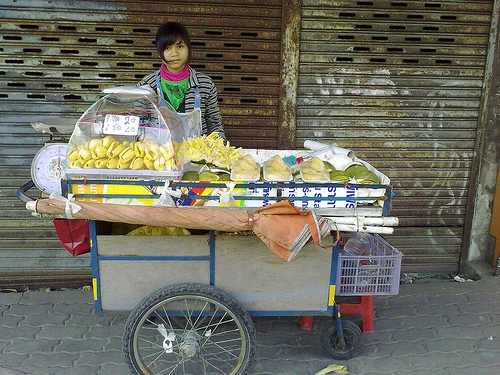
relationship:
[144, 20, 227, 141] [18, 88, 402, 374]
woman standing by food cart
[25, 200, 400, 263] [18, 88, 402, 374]
umbrella on side of food cart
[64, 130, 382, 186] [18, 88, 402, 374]
food on top of food cart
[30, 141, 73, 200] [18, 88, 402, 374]
scale on edge of food cart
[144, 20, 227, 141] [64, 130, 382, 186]
woman selling food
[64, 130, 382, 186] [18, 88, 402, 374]
food on food cart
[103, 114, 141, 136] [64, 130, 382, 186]
tag for food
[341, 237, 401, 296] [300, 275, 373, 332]
basket sitting on stool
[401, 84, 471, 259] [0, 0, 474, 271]
graffiti on wall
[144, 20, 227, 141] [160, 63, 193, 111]
woman has on scarf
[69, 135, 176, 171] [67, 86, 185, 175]
food in container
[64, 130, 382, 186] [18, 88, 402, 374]
food in food cart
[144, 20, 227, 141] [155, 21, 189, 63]
woman has hair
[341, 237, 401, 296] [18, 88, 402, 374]
basket in front of food cart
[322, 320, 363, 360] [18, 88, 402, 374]
front wheel of food cart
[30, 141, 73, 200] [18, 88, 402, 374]
scale on food cart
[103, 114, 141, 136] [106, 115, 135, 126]
tag with price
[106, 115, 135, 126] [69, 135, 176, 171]
price of food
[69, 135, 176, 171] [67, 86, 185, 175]
food covered with cover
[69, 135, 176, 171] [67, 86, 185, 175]
bananas are under dome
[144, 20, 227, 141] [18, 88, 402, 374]
woman manning food cart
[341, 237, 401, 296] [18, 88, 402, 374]
basket on food cart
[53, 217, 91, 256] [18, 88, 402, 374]
bag on food cart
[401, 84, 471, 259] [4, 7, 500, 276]
graffiti on building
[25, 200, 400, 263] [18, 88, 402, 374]
umbrella on food cart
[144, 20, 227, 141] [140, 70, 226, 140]
woman wearing shirt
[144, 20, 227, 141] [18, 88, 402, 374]
woman standing behind food cart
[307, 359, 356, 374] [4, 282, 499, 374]
trash laying on sidewalk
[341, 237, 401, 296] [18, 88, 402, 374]
basket on front of food cart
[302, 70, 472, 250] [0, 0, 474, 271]
painting on wall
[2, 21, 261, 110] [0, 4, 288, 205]
holes are in siding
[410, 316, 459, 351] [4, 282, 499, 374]
stones are on path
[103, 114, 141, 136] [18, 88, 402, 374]
tag on side of food cart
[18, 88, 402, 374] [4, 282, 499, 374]
food cart on sidewalk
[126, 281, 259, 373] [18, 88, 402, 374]
wheel on food cart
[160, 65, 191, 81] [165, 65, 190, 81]
fabric around neck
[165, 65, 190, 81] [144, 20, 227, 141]
neck of woman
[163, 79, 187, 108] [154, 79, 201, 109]
fabric on chest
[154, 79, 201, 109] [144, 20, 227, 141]
chest of woman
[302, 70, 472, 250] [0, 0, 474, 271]
markings are on wall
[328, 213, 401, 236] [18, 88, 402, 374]
pole on side of food cart